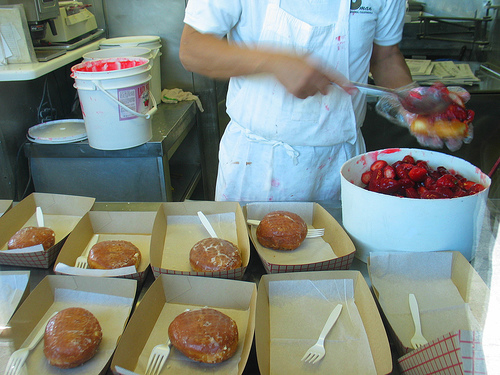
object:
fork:
[301, 300, 343, 363]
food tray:
[152, 198, 253, 277]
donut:
[187, 238, 243, 273]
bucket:
[337, 147, 489, 266]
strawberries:
[370, 160, 385, 170]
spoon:
[333, 84, 450, 119]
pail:
[338, 149, 491, 266]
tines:
[297, 351, 321, 364]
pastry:
[83, 241, 141, 272]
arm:
[179, 0, 274, 78]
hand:
[268, 55, 360, 100]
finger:
[323, 69, 361, 94]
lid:
[27, 119, 89, 143]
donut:
[411, 104, 467, 138]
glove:
[375, 83, 474, 150]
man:
[174, 1, 469, 201]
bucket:
[69, 59, 149, 152]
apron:
[213, 0, 363, 205]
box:
[396, 332, 481, 375]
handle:
[142, 105, 164, 119]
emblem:
[346, 0, 377, 15]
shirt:
[180, 0, 403, 139]